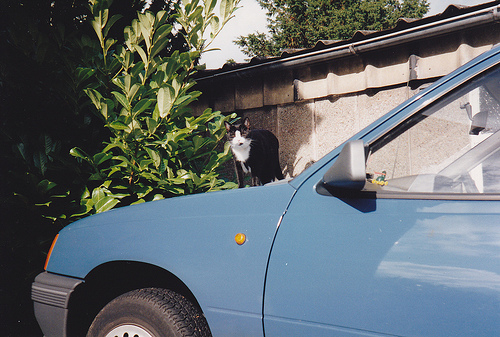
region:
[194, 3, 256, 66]
the sky through the trees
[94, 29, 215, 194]
leaves on the tree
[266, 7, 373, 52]
a tree behind the wall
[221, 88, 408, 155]
a cement wall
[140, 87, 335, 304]
a cat on top of the car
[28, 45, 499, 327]
a blue car in front of a wall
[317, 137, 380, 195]
a mirror on the side of the car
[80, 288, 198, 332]
the tire on the car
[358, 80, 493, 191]
the window in the car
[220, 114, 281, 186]
a black and white cat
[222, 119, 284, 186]
Black and white cat standing on car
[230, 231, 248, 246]
Reflector on car fender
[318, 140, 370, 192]
Rearview mirror on driver side door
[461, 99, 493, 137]
Rearview mirror mounted on windshield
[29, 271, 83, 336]
Gray bumper on car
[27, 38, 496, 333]
Blue car parked near building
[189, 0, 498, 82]
Slanted roof on building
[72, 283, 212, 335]
Front tire on blue car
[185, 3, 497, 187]
Concrete building in background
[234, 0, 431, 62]
Tree in background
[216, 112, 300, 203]
A black and white cat on the hood of a blue car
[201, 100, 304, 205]
cat stands on a car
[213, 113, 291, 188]
cat is black and white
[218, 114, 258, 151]
head of cat is black and white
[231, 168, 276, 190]
legs of cat are black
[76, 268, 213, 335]
front wheel of car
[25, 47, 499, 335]
the car is blue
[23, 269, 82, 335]
bumper is color gray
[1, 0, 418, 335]
a plant in front a car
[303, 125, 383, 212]
gray mirror on side the car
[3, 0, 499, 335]
car on side a wall